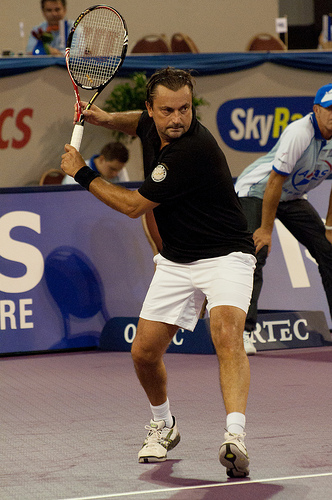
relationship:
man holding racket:
[59, 64, 275, 479] [63, 3, 132, 150]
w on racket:
[79, 20, 119, 64] [63, 3, 132, 150]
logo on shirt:
[151, 163, 174, 186] [130, 107, 259, 256]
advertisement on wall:
[1, 90, 314, 158] [1, 38, 329, 193]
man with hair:
[59, 64, 275, 479] [139, 64, 198, 105]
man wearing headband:
[59, 64, 275, 479] [149, 74, 187, 82]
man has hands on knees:
[236, 79, 328, 356] [253, 239, 332, 264]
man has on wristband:
[59, 64, 275, 479] [72, 164, 105, 193]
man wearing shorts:
[59, 64, 275, 479] [138, 250, 261, 331]